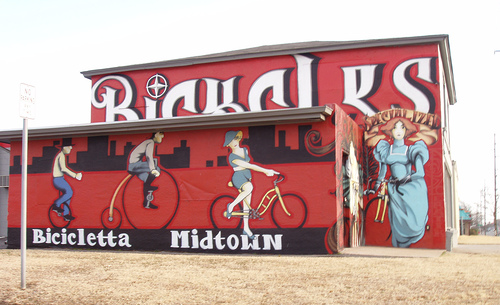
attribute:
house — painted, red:
[3, 34, 468, 259]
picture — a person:
[353, 104, 441, 247]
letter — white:
[338, 58, 385, 119]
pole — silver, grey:
[18, 116, 32, 293]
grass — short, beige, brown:
[3, 234, 500, 304]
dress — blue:
[370, 140, 434, 247]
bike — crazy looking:
[102, 165, 179, 232]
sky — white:
[4, 1, 495, 225]